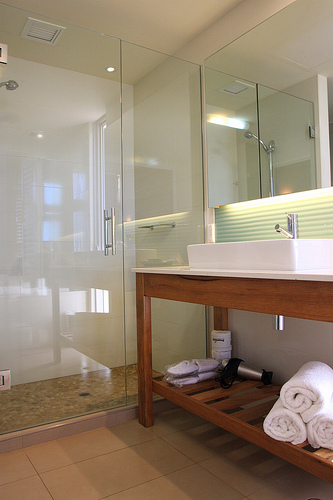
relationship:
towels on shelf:
[266, 369, 331, 447] [179, 404, 319, 472]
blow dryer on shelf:
[222, 354, 271, 385] [179, 404, 319, 472]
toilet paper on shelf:
[203, 324, 235, 364] [179, 404, 319, 472]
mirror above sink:
[209, 63, 330, 183] [202, 236, 316, 261]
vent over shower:
[24, 18, 66, 51] [13, 70, 120, 354]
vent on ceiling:
[24, 18, 66, 51] [8, 9, 201, 74]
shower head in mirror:
[243, 123, 278, 152] [209, 63, 330, 183]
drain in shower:
[76, 389, 97, 403] [13, 70, 120, 354]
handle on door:
[104, 210, 120, 255] [91, 161, 131, 321]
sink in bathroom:
[202, 236, 316, 261] [27, 65, 325, 405]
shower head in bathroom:
[243, 123, 278, 152] [27, 65, 325, 405]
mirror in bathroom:
[209, 63, 330, 183] [27, 65, 325, 405]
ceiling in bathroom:
[8, 9, 201, 74] [27, 65, 325, 405]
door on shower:
[91, 161, 131, 321] [13, 70, 120, 354]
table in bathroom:
[148, 267, 331, 292] [27, 65, 325, 405]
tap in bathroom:
[276, 224, 288, 237] [27, 65, 325, 405]